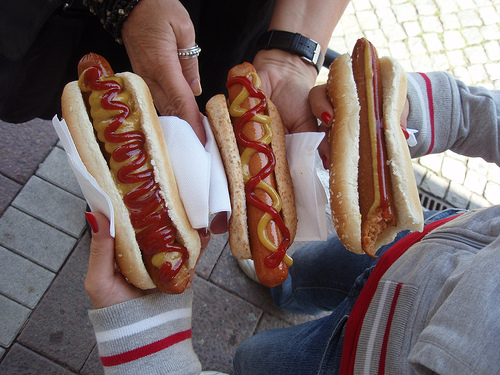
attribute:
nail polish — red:
[81, 210, 100, 238]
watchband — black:
[259, 22, 323, 65]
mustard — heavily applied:
[80, 76, 187, 268]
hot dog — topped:
[328, 35, 426, 259]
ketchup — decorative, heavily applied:
[84, 66, 189, 280]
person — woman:
[0, 0, 355, 194]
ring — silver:
[177, 44, 203, 61]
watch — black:
[253, 27, 326, 77]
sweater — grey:
[87, 71, 500, 374]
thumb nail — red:
[83, 211, 98, 233]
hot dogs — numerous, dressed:
[60, 38, 424, 295]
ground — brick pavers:
[2, 1, 499, 374]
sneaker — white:
[236, 257, 260, 283]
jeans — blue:
[234, 207, 473, 374]